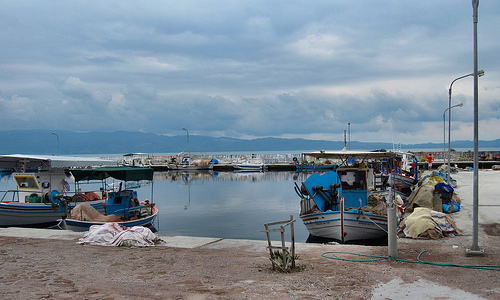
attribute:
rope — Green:
[322, 247, 499, 269]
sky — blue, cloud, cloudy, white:
[85, 17, 260, 98]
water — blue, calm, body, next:
[222, 184, 287, 222]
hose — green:
[318, 241, 487, 273]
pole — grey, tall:
[442, 9, 492, 256]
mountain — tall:
[11, 120, 175, 160]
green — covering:
[63, 155, 160, 188]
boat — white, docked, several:
[11, 156, 180, 233]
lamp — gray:
[432, 53, 488, 162]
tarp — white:
[84, 218, 160, 251]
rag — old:
[73, 207, 167, 260]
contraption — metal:
[368, 191, 424, 265]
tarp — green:
[64, 164, 157, 199]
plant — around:
[244, 238, 312, 277]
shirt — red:
[423, 147, 440, 168]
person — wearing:
[417, 138, 449, 180]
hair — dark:
[428, 150, 436, 160]